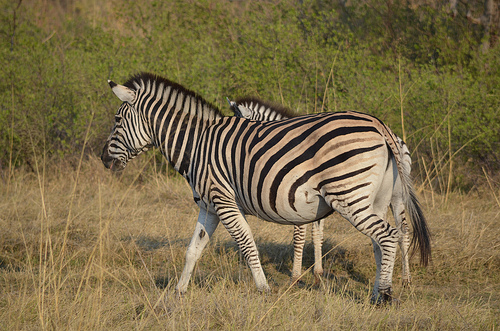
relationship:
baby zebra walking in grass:
[230, 89, 427, 279] [289, 243, 381, 323]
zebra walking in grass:
[81, 60, 434, 304] [0, 53, 500, 330]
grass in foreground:
[9, 168, 174, 306] [0, 206, 489, 328]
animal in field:
[98, 75, 425, 301] [1, 149, 498, 324]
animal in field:
[100, 71, 434, 309] [0, 169, 494, 329]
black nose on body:
[96, 142, 107, 170] [95, 63, 435, 311]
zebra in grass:
[81, 60, 434, 304] [0, 145, 499, 329]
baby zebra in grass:
[226, 91, 415, 282] [0, 145, 499, 329]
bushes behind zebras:
[0, 0, 498, 174] [99, 73, 430, 306]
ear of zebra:
[94, 72, 146, 104] [67, 50, 448, 297]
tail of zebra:
[378, 117, 436, 267] [81, 60, 434, 304]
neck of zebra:
[147, 77, 214, 191] [81, 60, 434, 304]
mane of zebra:
[119, 68, 227, 130] [81, 60, 434, 304]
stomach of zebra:
[238, 187, 335, 226] [100, 70, 437, 310]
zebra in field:
[103, 75, 420, 267] [30, 52, 490, 323]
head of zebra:
[92, 66, 157, 173] [81, 60, 434, 304]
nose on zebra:
[100, 139, 124, 171] [100, 70, 437, 310]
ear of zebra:
[107, 77, 137, 104] [97, 74, 410, 307]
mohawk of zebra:
[103, 64, 251, 123] [100, 70, 437, 310]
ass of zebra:
[321, 111, 404, 210] [100, 70, 437, 310]